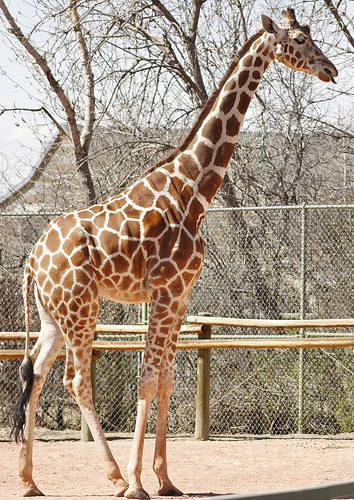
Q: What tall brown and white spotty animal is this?
A: Giraffe.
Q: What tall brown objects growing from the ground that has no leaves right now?
A: Tree.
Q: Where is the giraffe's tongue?
A: Sticking out.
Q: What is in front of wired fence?
A: Wooden post fence.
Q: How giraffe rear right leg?
A: Stepping forward.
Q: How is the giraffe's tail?
A: Brown, tan, and black.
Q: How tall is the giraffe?
A: Taller than both fences.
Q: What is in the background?
A: Building.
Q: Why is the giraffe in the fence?
A: Standing.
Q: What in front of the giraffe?
A: A fence.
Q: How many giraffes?
A: 1.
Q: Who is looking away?
A: The tall giraffe.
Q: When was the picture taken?
A: Daytime.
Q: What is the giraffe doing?
A: Looking away.